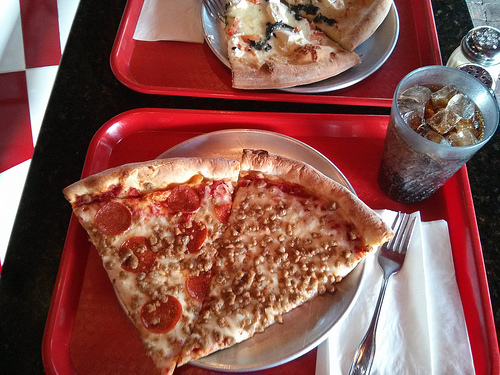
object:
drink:
[376, 62, 500, 206]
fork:
[346, 208, 419, 372]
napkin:
[313, 207, 478, 375]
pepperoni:
[89, 199, 135, 236]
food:
[215, 0, 394, 91]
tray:
[108, 0, 445, 109]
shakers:
[447, 25, 500, 97]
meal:
[40, 63, 500, 375]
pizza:
[60, 151, 245, 375]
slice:
[174, 142, 395, 374]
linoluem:
[0, 0, 84, 279]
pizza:
[224, 0, 396, 92]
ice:
[396, 82, 487, 147]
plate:
[135, 125, 368, 373]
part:
[418, 217, 500, 375]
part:
[353, 297, 384, 375]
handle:
[348, 277, 392, 374]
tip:
[145, 332, 192, 375]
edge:
[109, 280, 133, 317]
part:
[403, 222, 417, 232]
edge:
[292, 328, 334, 358]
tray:
[38, 105, 499, 375]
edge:
[107, 55, 155, 95]